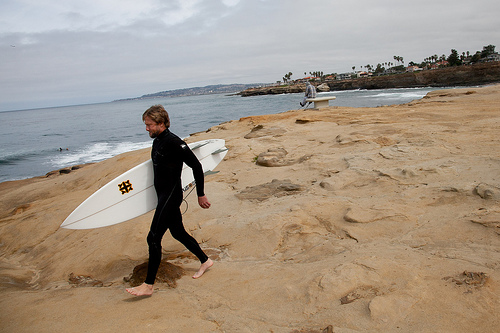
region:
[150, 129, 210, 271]
the swimsuit is black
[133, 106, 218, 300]
the man is barefoot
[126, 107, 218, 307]
the man is carrying a surfboard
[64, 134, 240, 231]
the surfboard is white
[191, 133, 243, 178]
the fins are three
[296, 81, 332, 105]
the man is seated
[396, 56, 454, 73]
buildings are on the shore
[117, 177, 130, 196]
logo is on the surfboard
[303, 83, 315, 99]
the jumper is grey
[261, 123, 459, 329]
the ground is unleveled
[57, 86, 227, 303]
man holding surfboard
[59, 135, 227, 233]
white surfboard being carried.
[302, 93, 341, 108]
bench on the beach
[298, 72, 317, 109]
person sitting on the bench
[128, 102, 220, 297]
black wet suit on the man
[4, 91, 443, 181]
water in the background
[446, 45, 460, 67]
tree in the background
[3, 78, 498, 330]
sand covering the beach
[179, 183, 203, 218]
cord attached to surfboard.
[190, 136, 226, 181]
fins on the surfboard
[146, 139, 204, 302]
this is a man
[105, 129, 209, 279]
this is a surfer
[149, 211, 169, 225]
this is a uniform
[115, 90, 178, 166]
this is a head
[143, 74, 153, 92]
the hair is blonde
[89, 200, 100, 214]
this is a surfboard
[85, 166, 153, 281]
the surfboard is white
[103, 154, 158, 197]
this is a logo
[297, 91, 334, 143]
this is a bench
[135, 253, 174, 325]
this is a foot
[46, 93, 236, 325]
this is a surfer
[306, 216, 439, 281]
this is a rock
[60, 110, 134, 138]
this is the water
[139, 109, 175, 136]
this is the head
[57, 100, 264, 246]
he is carrying a surfing board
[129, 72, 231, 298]
he is wearing a black attire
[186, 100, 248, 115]
the water is colourless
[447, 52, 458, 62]
these are trees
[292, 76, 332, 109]
the man is sitting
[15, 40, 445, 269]
this is on a coast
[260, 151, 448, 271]
the ground is lumpy here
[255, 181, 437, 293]
the ground is sandy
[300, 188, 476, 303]
the sandy ground is light brown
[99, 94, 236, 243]
this is a surfer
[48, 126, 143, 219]
this is a surfboard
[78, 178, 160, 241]
the surf board is white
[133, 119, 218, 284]
the surfer has a wetsuit on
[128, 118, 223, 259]
the wetsuit is all black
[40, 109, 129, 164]
this is the ocean